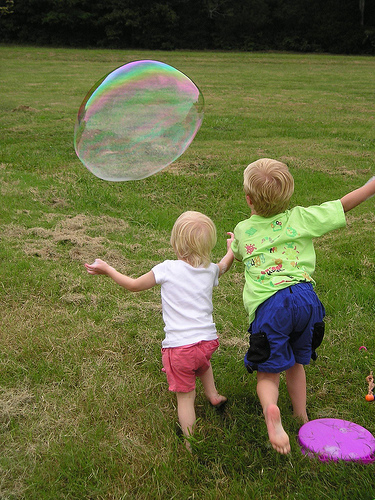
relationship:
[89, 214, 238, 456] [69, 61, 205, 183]
girl chasing bubble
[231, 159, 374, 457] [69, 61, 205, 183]
boy chasing bubble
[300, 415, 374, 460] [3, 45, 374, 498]
frisbee on grass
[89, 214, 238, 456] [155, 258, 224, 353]
girl wearing shirt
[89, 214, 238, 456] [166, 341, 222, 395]
girl wearing shorts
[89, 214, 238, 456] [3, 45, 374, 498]
girl in grass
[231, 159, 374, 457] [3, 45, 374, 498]
boy in grass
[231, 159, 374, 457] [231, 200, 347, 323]
boy wearing tshirt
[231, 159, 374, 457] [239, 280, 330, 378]
boy wearing shorts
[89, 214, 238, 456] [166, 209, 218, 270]
girl has hair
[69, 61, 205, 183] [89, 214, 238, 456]
bubble over girl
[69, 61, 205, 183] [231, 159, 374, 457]
bubble over boy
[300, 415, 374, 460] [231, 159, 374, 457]
frisbee behind boy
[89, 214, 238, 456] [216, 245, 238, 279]
girl has arm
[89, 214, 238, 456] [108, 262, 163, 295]
girl has arm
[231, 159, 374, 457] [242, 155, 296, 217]
boy has hair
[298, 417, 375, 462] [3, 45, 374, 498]
frisbee in grass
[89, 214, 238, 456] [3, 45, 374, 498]
girl on grass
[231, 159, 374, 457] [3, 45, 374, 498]
boy on grass